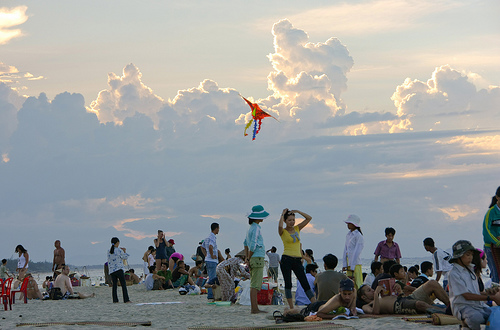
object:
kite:
[235, 93, 278, 141]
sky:
[0, 0, 499, 262]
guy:
[356, 275, 445, 314]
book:
[375, 278, 397, 297]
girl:
[242, 204, 270, 313]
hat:
[246, 205, 271, 220]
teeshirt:
[278, 220, 301, 257]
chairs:
[10, 273, 35, 305]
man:
[51, 264, 95, 299]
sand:
[0, 268, 486, 329]